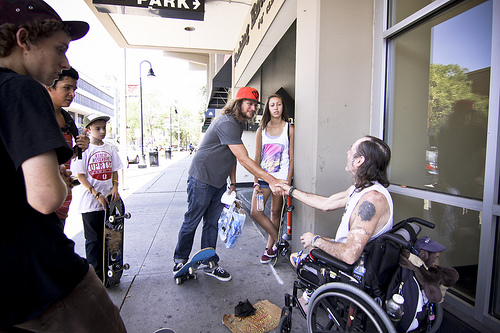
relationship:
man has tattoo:
[272, 137, 406, 316] [352, 198, 377, 221]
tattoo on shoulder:
[358, 200, 375, 222] [363, 191, 389, 213]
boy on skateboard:
[74, 111, 126, 283] [101, 196, 131, 286]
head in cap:
[228, 80, 263, 125] [234, 81, 266, 103]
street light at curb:
[138, 59, 153, 166] [121, 151, 186, 198]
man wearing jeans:
[172, 87, 289, 280] [174, 177, 221, 263]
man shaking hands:
[172, 87, 289, 280] [265, 170, 292, 203]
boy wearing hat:
[168, 85, 286, 287] [226, 81, 266, 111]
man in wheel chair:
[272, 137, 406, 316] [264, 212, 455, 322]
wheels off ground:
[183, 254, 214, 271] [52, 132, 322, 331]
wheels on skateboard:
[183, 254, 214, 271] [168, 244, 219, 286]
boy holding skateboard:
[74, 111, 126, 283] [102, 189, 128, 294]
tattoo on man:
[358, 200, 375, 222] [341, 130, 395, 198]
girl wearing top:
[249, 89, 296, 266] [257, 124, 288, 182]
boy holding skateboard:
[74, 113, 129, 283] [82, 186, 138, 296]